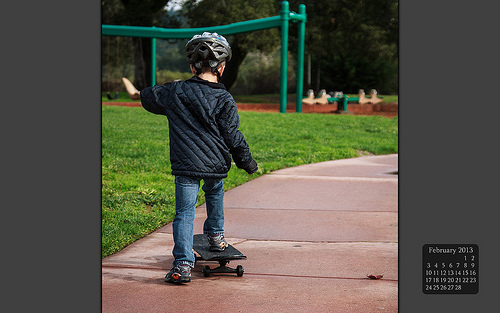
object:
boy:
[121, 31, 263, 284]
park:
[100, 1, 399, 313]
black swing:
[105, 34, 120, 100]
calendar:
[421, 243, 480, 294]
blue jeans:
[171, 175, 225, 268]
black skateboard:
[192, 233, 247, 277]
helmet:
[183, 31, 232, 83]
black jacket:
[139, 76, 259, 179]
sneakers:
[163, 234, 229, 283]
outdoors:
[129, 28, 394, 293]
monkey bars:
[102, 1, 308, 115]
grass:
[101, 98, 397, 242]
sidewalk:
[101, 169, 397, 304]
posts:
[278, 1, 307, 114]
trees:
[100, 0, 400, 94]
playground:
[101, 100, 398, 117]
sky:
[156, 1, 194, 14]